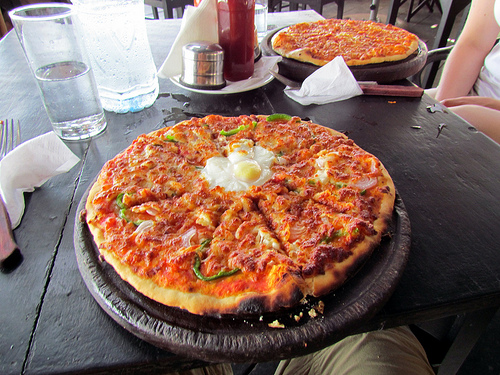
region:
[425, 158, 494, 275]
the wood is brown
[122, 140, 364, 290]
the pizza is tasty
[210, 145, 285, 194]
there is egg of the pizza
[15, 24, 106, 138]
the glass is half water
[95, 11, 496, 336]
there are two pieces of pizza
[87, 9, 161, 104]
the water bottle has water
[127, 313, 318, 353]
the plate is wooden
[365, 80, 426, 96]
the handle is wooden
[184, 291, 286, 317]
there is crust on the pizza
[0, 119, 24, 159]
the fork is facing upward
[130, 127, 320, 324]
A pizza is visible.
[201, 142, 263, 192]
an egg sunnyside up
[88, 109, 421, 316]
pizza on top of a brown tray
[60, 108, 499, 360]
pizza on top of a brown table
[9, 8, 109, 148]
a clear water glass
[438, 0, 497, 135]
a person's arm and leg off to side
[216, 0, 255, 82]
ketchup bottle on table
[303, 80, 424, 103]
a piece of silverware with brown handle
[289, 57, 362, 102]
a used white napkin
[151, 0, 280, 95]
condiments on top of a white plate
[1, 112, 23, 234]
a fork and a napkin on table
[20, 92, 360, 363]
A pizza is visible.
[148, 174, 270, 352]
A pizza is visible.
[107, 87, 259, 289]
A pizza is visible.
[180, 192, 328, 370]
A pizza is visible.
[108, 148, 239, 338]
A pizza is visible.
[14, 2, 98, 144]
tall glass of water half full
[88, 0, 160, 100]
pitcher of water next to glass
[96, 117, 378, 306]
large pizza pie on table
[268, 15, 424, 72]
large pizza pie on table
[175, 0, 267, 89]
silver and red bottles on plate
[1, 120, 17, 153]
silver fork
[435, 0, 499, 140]
person sitting at the table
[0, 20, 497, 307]
dark brown wooden table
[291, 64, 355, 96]
white napkin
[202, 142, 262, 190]
fried egg in middle of pizza